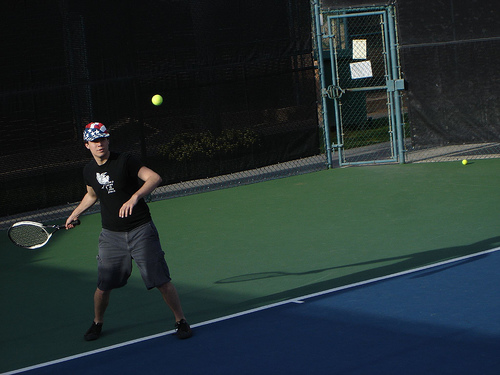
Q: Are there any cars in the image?
A: No, there are no cars.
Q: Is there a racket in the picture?
A: Yes, there is a racket.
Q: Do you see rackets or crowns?
A: Yes, there is a racket.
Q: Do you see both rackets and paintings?
A: No, there is a racket but no paintings.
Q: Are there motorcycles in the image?
A: No, there are no motorcycles.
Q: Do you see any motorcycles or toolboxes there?
A: No, there are no motorcycles or toolboxes.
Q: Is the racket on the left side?
A: Yes, the racket is on the left of the image.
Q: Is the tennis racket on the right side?
A: No, the tennis racket is on the left of the image.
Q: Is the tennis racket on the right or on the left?
A: The tennis racket is on the left of the image.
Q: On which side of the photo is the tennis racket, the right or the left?
A: The tennis racket is on the left of the image.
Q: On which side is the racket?
A: The racket is on the left of the image.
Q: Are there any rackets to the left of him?
A: Yes, there is a racket to the left of the man.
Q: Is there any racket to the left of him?
A: Yes, there is a racket to the left of the man.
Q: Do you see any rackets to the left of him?
A: Yes, there is a racket to the left of the man.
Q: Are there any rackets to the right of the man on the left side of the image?
A: No, the racket is to the left of the man.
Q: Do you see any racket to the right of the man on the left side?
A: No, the racket is to the left of the man.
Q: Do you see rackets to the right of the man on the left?
A: No, the racket is to the left of the man.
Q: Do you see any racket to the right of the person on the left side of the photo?
A: No, the racket is to the left of the man.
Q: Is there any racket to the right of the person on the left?
A: No, the racket is to the left of the man.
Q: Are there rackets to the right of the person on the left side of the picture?
A: No, the racket is to the left of the man.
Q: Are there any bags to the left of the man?
A: No, there is a racket to the left of the man.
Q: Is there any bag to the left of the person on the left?
A: No, there is a racket to the left of the man.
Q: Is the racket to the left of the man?
A: Yes, the racket is to the left of the man.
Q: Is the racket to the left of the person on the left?
A: Yes, the racket is to the left of the man.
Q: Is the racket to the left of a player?
A: No, the racket is to the left of the man.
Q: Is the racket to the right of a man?
A: No, the racket is to the left of a man.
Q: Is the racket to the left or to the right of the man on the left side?
A: The racket is to the left of the man.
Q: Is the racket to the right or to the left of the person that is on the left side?
A: The racket is to the left of the man.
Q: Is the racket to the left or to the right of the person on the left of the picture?
A: The racket is to the left of the man.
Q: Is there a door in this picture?
A: Yes, there is a door.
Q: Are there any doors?
A: Yes, there is a door.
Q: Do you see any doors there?
A: Yes, there is a door.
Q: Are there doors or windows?
A: Yes, there is a door.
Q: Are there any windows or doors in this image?
A: Yes, there is a door.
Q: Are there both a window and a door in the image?
A: No, there is a door but no windows.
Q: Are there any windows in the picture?
A: No, there are no windows.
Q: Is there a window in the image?
A: No, there are no windows.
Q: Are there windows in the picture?
A: No, there are no windows.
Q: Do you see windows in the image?
A: No, there are no windows.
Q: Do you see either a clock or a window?
A: No, there are no windows or clocks.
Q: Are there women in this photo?
A: No, there are no women.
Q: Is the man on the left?
A: Yes, the man is on the left of the image.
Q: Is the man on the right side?
A: No, the man is on the left of the image.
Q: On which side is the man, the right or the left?
A: The man is on the left of the image.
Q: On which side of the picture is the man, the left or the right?
A: The man is on the left of the image.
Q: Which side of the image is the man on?
A: The man is on the left of the image.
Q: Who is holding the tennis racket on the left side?
A: The man is holding the racket.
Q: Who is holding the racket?
A: The man is holding the racket.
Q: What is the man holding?
A: The man is holding the racket.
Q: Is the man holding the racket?
A: Yes, the man is holding the racket.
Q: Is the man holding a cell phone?
A: No, the man is holding the racket.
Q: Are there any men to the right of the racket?
A: Yes, there is a man to the right of the racket.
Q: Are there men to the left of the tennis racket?
A: No, the man is to the right of the tennis racket.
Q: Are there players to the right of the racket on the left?
A: No, there is a man to the right of the tennis racket.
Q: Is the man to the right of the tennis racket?
A: Yes, the man is to the right of the tennis racket.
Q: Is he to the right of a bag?
A: No, the man is to the right of the tennis racket.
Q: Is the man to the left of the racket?
A: No, the man is to the right of the racket.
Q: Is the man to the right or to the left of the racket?
A: The man is to the right of the racket.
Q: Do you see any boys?
A: No, there are no boys.